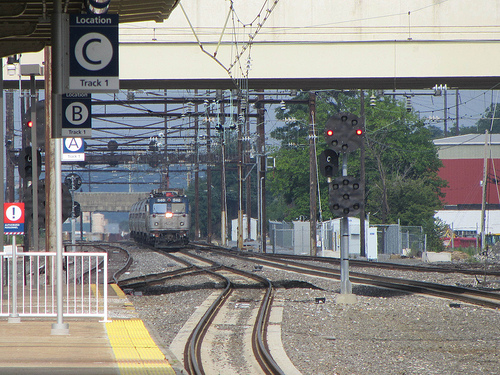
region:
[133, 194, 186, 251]
front of commuter train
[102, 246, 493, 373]
rails of train tracks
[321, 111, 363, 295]
glowing lights on pole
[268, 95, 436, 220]
green leaves on tree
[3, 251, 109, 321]
poles on metal railing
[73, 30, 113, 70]
letter in white circle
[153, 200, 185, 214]
two windows on front of train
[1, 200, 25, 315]
red and blue sign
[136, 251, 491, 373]
gravel in between train tracks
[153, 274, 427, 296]
shadow over train tracks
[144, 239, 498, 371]
gray metal train tracks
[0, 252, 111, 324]
white metal fence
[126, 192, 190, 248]
blue and gray train on tracks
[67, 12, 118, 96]
black and white signboard with letter C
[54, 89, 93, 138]
black and white signboard with letter B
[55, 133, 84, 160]
blue and white signboard with letter A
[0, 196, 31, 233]
red and blue warning signboard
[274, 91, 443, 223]
big green tree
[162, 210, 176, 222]
front light of train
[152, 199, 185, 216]
two small windshields of train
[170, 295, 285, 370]
set of metal train tracks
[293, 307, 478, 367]
ground covered in grey gravel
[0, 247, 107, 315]
white metal guard railing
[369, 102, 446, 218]
tree covered in green leaves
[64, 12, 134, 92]
black and white sign hanging from pole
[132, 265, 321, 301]
shadow of metal pole on ground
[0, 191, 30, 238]
red and blue warning sign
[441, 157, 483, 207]
red shingles on building roof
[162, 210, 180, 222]
light on front of train engine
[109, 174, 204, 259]
silver and blue train on tracks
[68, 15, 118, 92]
train information sign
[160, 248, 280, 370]
metal train tracks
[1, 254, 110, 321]
a short white metal fence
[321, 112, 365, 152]
two red lights are shining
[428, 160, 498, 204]
a red stripe on the building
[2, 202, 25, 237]
red and white and blue sign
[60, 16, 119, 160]
letters on the signs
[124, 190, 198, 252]
a train on the tracks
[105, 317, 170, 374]
yellow edge on the platform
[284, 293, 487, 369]
gravel in between the tracks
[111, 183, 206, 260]
train driving on tracks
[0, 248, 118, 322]
silver metal guard railing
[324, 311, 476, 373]
ground covered in grey rocks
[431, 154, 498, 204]
building roof with red shingles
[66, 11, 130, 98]
black and white sign hanging from train platform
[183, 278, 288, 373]
set of metal train tracks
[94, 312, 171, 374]
yellow line painted on train platform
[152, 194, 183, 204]
white writing on front of train engine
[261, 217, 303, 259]
silver metal chain length fencing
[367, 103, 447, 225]
large tree covered in bright green leaves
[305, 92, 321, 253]
An old wooden post.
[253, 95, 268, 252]
An old wooden post.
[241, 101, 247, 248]
An old wooden post.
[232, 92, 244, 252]
An old wooden post.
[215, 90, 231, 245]
An old wooden post.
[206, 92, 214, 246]
An old wooden post.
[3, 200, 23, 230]
red sign with exclamation point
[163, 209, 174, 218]
head light on train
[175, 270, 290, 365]
curve in rails of train track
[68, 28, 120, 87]
black sign for station C